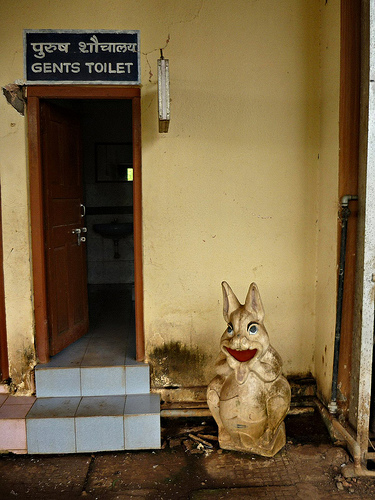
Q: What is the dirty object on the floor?
A: Rabbit.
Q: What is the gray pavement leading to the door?
A: Steps.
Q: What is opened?
A: Door.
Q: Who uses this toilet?
A: Gents.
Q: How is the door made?
A: Of brown wood.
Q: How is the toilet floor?
A: Blue ceramic tiles.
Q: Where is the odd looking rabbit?
A: Next to the steps.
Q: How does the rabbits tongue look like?
A: Red.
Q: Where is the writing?
A: On top of the door.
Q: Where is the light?
A: On the brown wall.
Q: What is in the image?
A: Rabbit doll.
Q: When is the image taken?
A: Door is open.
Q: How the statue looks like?
A: Ceramic.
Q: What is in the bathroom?
A: Entryway.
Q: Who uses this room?
A: Man.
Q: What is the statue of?
A: Rabbit.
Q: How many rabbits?
A: One.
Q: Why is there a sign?
A: To know man or woman toilet.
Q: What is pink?
A: Step to the left.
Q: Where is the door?
A: Below the sign.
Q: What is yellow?
A: Walls.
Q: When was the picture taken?
A: Daytime.